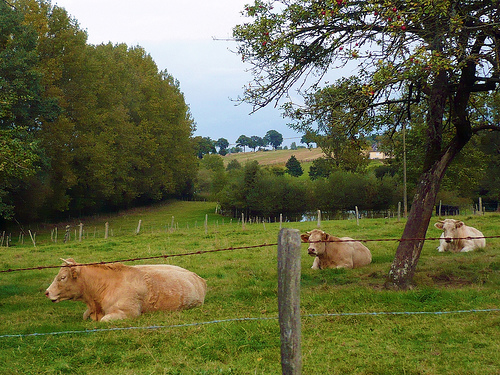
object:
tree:
[205, 0, 499, 290]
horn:
[52, 252, 77, 274]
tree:
[262, 128, 282, 153]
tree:
[245, 135, 266, 153]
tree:
[232, 135, 250, 153]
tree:
[213, 136, 229, 153]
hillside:
[215, 147, 336, 181]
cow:
[43, 258, 209, 328]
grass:
[458, 319, 487, 342]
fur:
[109, 277, 166, 294]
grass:
[0, 237, 132, 257]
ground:
[143, 200, 205, 215]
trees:
[190, 128, 284, 155]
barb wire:
[309, 234, 498, 247]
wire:
[0, 234, 499, 274]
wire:
[0, 308, 500, 340]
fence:
[0, 235, 498, 375]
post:
[276, 224, 303, 373]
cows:
[299, 229, 373, 270]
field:
[119, 224, 218, 249]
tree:
[3, 0, 208, 214]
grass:
[310, 331, 413, 372]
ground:
[430, 265, 467, 284]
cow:
[433, 217, 487, 253]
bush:
[214, 176, 253, 216]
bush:
[247, 161, 297, 213]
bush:
[288, 172, 333, 214]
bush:
[318, 165, 397, 212]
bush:
[193, 152, 231, 202]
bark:
[416, 170, 435, 200]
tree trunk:
[386, 169, 443, 291]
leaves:
[132, 182, 139, 191]